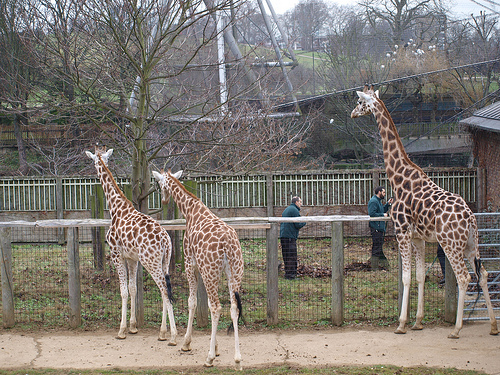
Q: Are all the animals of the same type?
A: Yes, all the animals are giraffes.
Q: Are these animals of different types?
A: No, all the animals are giraffes.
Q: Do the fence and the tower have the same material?
A: No, the fence is made of wood and the tower is made of metal.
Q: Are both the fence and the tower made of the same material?
A: No, the fence is made of wood and the tower is made of metal.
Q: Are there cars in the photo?
A: No, there are no cars.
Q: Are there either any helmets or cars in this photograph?
A: No, there are no cars or helmets.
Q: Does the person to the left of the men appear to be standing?
A: Yes, the person is standing.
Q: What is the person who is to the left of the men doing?
A: The person is standing.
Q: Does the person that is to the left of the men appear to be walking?
A: No, the person is standing.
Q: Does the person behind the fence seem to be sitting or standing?
A: The person is standing.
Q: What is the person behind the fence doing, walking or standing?
A: The person is standing.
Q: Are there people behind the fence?
A: Yes, there is a person behind the fence.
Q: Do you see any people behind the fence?
A: Yes, there is a person behind the fence.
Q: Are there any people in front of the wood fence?
A: No, the person is behind the fence.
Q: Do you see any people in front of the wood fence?
A: No, the person is behind the fence.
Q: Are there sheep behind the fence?
A: No, there is a person behind the fence.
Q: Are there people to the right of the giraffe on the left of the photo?
A: Yes, there is a person to the right of the giraffe.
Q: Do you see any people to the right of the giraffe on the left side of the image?
A: Yes, there is a person to the right of the giraffe.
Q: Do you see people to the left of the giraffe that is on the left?
A: No, the person is to the right of the giraffe.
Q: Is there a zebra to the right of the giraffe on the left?
A: No, there is a person to the right of the giraffe.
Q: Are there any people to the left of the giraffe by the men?
A: Yes, there is a person to the left of the giraffe.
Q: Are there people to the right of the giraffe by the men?
A: No, the person is to the left of the giraffe.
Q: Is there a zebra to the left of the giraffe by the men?
A: No, there is a person to the left of the giraffe.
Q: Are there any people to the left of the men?
A: Yes, there is a person to the left of the men.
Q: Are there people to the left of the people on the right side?
A: Yes, there is a person to the left of the men.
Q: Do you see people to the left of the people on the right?
A: Yes, there is a person to the left of the men.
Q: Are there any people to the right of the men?
A: No, the person is to the left of the men.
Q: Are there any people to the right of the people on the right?
A: No, the person is to the left of the men.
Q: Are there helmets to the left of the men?
A: No, there is a person to the left of the men.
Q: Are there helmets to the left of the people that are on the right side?
A: No, there is a person to the left of the men.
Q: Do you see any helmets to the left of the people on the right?
A: No, there is a person to the left of the men.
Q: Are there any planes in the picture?
A: No, there are no planes.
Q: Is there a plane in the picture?
A: No, there are no airplanes.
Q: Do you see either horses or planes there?
A: No, there are no planes or horses.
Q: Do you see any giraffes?
A: Yes, there is a giraffe.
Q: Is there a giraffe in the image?
A: Yes, there is a giraffe.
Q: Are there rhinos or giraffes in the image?
A: Yes, there is a giraffe.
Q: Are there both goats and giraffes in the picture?
A: No, there is a giraffe but no goats.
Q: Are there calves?
A: No, there are no calves.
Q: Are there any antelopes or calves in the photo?
A: No, there are no calves or antelopes.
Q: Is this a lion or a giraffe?
A: This is a giraffe.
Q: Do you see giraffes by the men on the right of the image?
A: Yes, there is a giraffe by the men.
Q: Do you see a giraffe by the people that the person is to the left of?
A: Yes, there is a giraffe by the men.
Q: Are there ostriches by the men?
A: No, there is a giraffe by the men.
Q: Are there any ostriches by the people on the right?
A: No, there is a giraffe by the men.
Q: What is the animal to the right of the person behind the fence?
A: The animal is a giraffe.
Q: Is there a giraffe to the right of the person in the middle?
A: Yes, there is a giraffe to the right of the person.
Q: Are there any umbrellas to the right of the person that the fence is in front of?
A: No, there is a giraffe to the right of the person.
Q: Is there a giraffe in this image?
A: Yes, there is a giraffe.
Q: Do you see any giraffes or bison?
A: Yes, there is a giraffe.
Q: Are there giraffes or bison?
A: Yes, there is a giraffe.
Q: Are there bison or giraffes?
A: Yes, there is a giraffe.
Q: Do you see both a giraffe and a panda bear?
A: No, there is a giraffe but no panda bears.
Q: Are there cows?
A: No, there are no cows.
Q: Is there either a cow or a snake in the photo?
A: No, there are no cows or snakes.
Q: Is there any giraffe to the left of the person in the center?
A: Yes, there is a giraffe to the left of the person.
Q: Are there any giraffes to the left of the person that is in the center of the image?
A: Yes, there is a giraffe to the left of the person.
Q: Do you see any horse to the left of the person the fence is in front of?
A: No, there is a giraffe to the left of the person.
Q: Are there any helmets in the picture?
A: No, there are no helmets.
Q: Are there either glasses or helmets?
A: No, there are no helmets or glasses.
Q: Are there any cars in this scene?
A: No, there are no cars.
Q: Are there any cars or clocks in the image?
A: No, there are no cars or clocks.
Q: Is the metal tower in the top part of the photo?
A: Yes, the tower is in the top of the image.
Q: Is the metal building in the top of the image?
A: Yes, the tower is in the top of the image.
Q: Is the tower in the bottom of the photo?
A: No, the tower is in the top of the image.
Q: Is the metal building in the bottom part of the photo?
A: No, the tower is in the top of the image.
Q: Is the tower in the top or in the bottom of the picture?
A: The tower is in the top of the image.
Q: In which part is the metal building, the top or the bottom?
A: The tower is in the top of the image.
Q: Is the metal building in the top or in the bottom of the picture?
A: The tower is in the top of the image.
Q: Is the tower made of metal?
A: Yes, the tower is made of metal.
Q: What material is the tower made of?
A: The tower is made of metal.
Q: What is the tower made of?
A: The tower is made of metal.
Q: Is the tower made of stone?
A: No, the tower is made of metal.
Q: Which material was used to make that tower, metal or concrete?
A: The tower is made of metal.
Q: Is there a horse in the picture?
A: No, there are no horses.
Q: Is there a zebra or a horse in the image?
A: No, there are no horses or zebras.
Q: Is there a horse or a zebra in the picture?
A: No, there are no horses or zebras.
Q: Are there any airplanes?
A: No, there are no airplanes.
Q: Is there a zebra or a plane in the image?
A: No, there are no airplanes or zebras.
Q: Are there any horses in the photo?
A: No, there are no horses.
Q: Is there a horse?
A: No, there are no horses.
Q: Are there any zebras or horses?
A: No, there are no horses or zebras.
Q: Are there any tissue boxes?
A: No, there are no tissue boxes.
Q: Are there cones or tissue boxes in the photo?
A: No, there are no tissue boxes or cones.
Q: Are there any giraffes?
A: Yes, there is a giraffe.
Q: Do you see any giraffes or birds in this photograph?
A: Yes, there is a giraffe.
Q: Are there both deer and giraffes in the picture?
A: No, there is a giraffe but no deer.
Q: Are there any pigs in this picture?
A: No, there are no pigs.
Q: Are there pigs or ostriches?
A: No, there are no pigs or ostriches.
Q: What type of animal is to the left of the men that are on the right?
A: The animal is a giraffe.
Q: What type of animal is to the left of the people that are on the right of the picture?
A: The animal is a giraffe.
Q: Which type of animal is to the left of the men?
A: The animal is a giraffe.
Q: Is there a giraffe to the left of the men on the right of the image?
A: Yes, there is a giraffe to the left of the men.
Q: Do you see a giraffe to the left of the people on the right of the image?
A: Yes, there is a giraffe to the left of the men.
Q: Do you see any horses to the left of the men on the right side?
A: No, there is a giraffe to the left of the men.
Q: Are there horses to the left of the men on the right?
A: No, there is a giraffe to the left of the men.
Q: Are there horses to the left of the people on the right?
A: No, there is a giraffe to the left of the men.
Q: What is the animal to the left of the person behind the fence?
A: The animal is a giraffe.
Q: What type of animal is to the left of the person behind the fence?
A: The animal is a giraffe.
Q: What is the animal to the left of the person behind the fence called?
A: The animal is a giraffe.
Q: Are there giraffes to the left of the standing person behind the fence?
A: Yes, there is a giraffe to the left of the person.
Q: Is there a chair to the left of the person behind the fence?
A: No, there is a giraffe to the left of the person.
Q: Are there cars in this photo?
A: No, there are no cars.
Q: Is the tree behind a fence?
A: Yes, the tree is behind a fence.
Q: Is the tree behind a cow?
A: No, the tree is behind a fence.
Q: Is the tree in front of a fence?
A: No, the tree is behind a fence.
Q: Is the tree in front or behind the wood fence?
A: The tree is behind the fence.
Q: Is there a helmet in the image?
A: No, there are no helmets.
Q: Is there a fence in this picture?
A: Yes, there is a fence.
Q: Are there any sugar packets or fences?
A: Yes, there is a fence.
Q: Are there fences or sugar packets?
A: Yes, there is a fence.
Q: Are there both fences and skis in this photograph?
A: No, there is a fence but no skis.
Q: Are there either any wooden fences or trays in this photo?
A: Yes, there is a wood fence.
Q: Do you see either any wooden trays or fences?
A: Yes, there is a wood fence.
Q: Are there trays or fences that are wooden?
A: Yes, the fence is wooden.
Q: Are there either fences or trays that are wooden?
A: Yes, the fence is wooden.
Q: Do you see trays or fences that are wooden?
A: Yes, the fence is wooden.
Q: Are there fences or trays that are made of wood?
A: Yes, the fence is made of wood.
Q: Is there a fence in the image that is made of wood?
A: Yes, there is a fence that is made of wood.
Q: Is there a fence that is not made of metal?
A: Yes, there is a fence that is made of wood.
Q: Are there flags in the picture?
A: No, there are no flags.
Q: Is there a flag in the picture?
A: No, there are no flags.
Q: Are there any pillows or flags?
A: No, there are no flags or pillows.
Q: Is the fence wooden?
A: Yes, the fence is wooden.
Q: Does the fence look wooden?
A: Yes, the fence is wooden.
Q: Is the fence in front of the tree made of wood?
A: Yes, the fence is made of wood.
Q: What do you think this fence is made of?
A: The fence is made of wood.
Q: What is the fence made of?
A: The fence is made of wood.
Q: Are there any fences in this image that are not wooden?
A: No, there is a fence but it is wooden.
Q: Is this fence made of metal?
A: No, the fence is made of wood.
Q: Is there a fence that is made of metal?
A: No, there is a fence but it is made of wood.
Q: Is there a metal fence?
A: No, there is a fence but it is made of wood.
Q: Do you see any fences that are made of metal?
A: No, there is a fence but it is made of wood.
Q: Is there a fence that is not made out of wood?
A: No, there is a fence but it is made of wood.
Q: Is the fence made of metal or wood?
A: The fence is made of wood.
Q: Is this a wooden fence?
A: Yes, this is a wooden fence.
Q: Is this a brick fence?
A: No, this is a wooden fence.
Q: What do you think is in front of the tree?
A: The fence is in front of the tree.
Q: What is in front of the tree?
A: The fence is in front of the tree.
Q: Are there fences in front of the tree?
A: Yes, there is a fence in front of the tree.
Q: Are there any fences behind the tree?
A: No, the fence is in front of the tree.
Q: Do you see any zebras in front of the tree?
A: No, there is a fence in front of the tree.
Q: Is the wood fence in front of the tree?
A: Yes, the fence is in front of the tree.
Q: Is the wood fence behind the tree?
A: No, the fence is in front of the tree.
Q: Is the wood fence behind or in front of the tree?
A: The fence is in front of the tree.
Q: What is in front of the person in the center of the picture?
A: The fence is in front of the person.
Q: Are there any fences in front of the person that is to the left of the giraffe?
A: Yes, there is a fence in front of the person.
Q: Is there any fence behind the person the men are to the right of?
A: No, the fence is in front of the person.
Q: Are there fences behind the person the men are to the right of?
A: No, the fence is in front of the person.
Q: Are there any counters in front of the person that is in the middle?
A: No, there is a fence in front of the person.